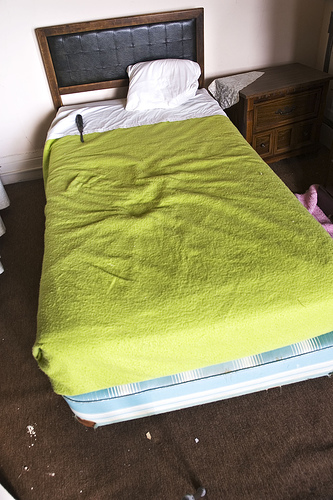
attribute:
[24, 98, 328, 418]
bed — white, made, blue, black, green, twin, neat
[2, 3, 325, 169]
wall — wide, close, clean, white, framed, brown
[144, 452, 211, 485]
floor — brown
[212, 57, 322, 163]
cabinet — brown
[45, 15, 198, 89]
cushion — black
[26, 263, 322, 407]
matress — blue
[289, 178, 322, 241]
clothing — pink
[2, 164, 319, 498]
floor — brown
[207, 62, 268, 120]
clothing — white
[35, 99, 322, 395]
bed spread — lime green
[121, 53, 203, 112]
bed pillow — white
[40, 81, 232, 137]
sheet — white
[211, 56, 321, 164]
table — bedside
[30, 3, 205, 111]
headboard — padded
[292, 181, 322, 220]
towel — pink, crumpled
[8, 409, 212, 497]
spots — white, dirty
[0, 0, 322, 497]
carpet — dark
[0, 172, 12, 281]
curtains — white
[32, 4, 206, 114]
head board — wooden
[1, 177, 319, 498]
carpet — brown